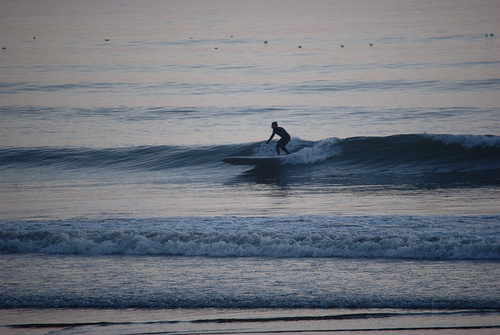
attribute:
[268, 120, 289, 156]
person — surfing, crouching, silhouetted, standing, alone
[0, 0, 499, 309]
water — dark, smooth, calm, blue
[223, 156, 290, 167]
surfboard — long, thin, white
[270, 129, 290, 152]
wetsuit — black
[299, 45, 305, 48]
object — small, floating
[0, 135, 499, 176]
wave — long, short, skinny, small, calm, medium, foaming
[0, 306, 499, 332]
shore — dark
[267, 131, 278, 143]
arm — extended